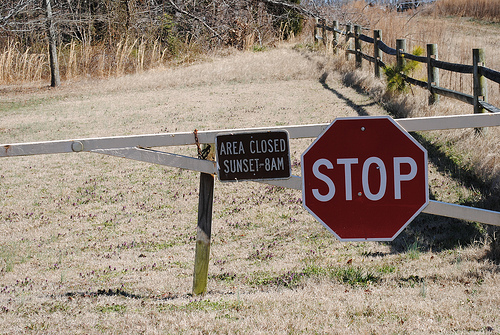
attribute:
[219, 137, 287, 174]
words — white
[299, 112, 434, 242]
stop sign — mounted, red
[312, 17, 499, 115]
fence — grey, wooden, brown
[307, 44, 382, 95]
grass — dry, tan, dead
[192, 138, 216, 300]
post — yellow, long, wooden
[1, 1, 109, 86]
pine — tall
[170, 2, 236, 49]
tree — fallen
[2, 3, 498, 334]
park — closed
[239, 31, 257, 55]
stump — brown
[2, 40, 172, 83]
brush — wild, dry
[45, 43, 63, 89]
trunk — long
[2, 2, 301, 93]
trees — wild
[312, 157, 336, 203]
s — large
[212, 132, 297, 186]
sign — black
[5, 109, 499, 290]
railings — white